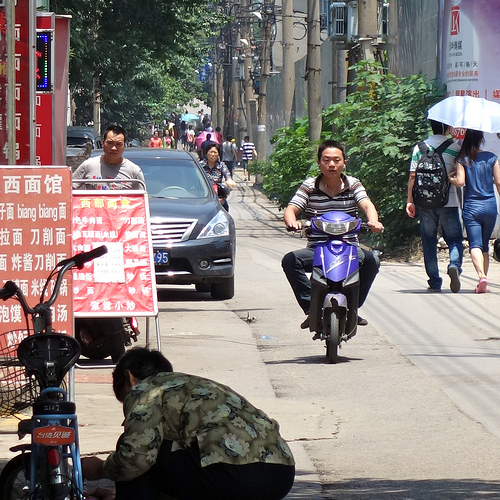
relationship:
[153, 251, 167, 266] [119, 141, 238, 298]
license plate on car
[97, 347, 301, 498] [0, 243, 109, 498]
lady has bike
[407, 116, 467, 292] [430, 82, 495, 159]
man holds umbrella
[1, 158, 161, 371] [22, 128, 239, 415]
signs on sidewalk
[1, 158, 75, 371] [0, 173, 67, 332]
signs has symbols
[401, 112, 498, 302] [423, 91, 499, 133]
people under umbrella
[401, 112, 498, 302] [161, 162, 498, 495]
people on road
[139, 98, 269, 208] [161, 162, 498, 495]
people on road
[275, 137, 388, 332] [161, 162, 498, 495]
man on road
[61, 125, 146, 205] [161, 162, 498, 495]
people on road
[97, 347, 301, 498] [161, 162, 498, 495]
lady on road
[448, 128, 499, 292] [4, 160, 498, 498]
person walking on street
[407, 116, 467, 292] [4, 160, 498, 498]
man walking on street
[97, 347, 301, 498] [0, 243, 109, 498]
lady next to bike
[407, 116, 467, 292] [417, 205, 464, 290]
man wearing jeans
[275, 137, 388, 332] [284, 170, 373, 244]
man wearing shirt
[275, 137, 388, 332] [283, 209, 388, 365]
man on moped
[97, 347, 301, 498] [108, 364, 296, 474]
lady wearing shirt